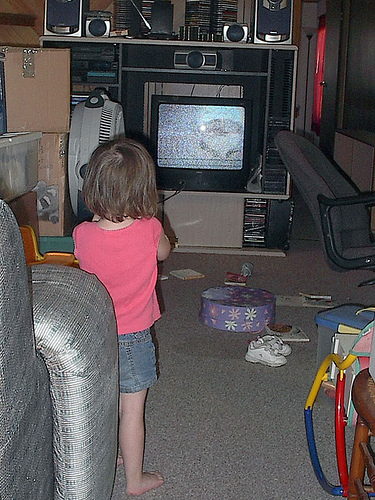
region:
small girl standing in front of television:
[59, 108, 255, 411]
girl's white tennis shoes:
[239, 331, 290, 371]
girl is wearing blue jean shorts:
[113, 327, 165, 402]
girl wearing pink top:
[76, 211, 165, 335]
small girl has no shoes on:
[112, 455, 173, 488]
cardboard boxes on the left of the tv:
[1, 30, 86, 240]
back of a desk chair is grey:
[270, 118, 371, 289]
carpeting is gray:
[182, 380, 259, 479]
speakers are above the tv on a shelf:
[38, 3, 294, 73]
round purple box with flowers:
[190, 285, 280, 333]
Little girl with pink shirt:
[80, 134, 164, 495]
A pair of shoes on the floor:
[244, 334, 291, 367]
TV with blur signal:
[149, 95, 255, 192]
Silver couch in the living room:
[0, 197, 120, 498]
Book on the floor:
[169, 266, 205, 280]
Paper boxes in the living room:
[1, 41, 69, 236]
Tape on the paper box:
[3, 46, 68, 77]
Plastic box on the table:
[0, 130, 42, 200]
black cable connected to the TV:
[155, 186, 182, 207]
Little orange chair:
[19, 222, 74, 264]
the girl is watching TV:
[70, 96, 323, 493]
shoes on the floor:
[242, 317, 307, 383]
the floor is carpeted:
[182, 365, 294, 480]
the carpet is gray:
[201, 365, 314, 490]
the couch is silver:
[2, 211, 151, 496]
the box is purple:
[194, 270, 270, 344]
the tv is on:
[142, 80, 266, 198]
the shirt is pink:
[57, 197, 190, 383]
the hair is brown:
[80, 149, 164, 213]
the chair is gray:
[263, 128, 371, 280]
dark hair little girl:
[90, 139, 163, 494]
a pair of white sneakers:
[239, 332, 296, 370]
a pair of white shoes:
[241, 331, 294, 376]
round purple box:
[195, 283, 278, 333]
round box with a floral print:
[201, 281, 276, 334]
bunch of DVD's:
[241, 195, 267, 250]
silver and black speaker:
[222, 20, 250, 41]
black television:
[153, 91, 249, 190]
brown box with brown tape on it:
[6, 41, 70, 132]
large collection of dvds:
[182, 1, 225, 40]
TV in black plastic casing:
[142, 84, 258, 199]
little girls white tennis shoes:
[240, 321, 297, 377]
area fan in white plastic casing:
[68, 84, 148, 238]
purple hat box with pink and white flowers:
[194, 279, 301, 339]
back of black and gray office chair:
[266, 114, 374, 268]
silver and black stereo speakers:
[84, 9, 114, 42]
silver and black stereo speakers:
[221, 18, 252, 52]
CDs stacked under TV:
[241, 193, 272, 252]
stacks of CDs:
[184, 1, 239, 41]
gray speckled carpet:
[181, 379, 287, 489]